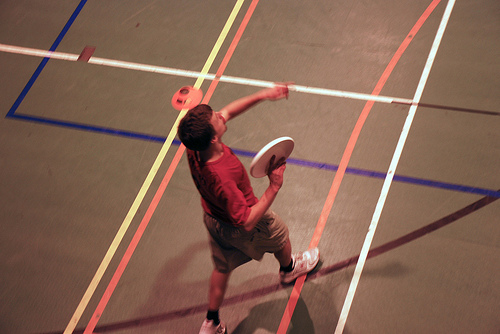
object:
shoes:
[198, 318, 226, 332]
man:
[176, 81, 317, 331]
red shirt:
[186, 141, 259, 228]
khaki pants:
[199, 208, 289, 274]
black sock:
[279, 259, 295, 274]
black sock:
[205, 309, 219, 325]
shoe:
[278, 247, 320, 282]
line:
[45, 22, 499, 333]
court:
[0, 0, 500, 334]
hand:
[267, 154, 286, 189]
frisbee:
[250, 136, 295, 178]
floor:
[5, 14, 482, 329]